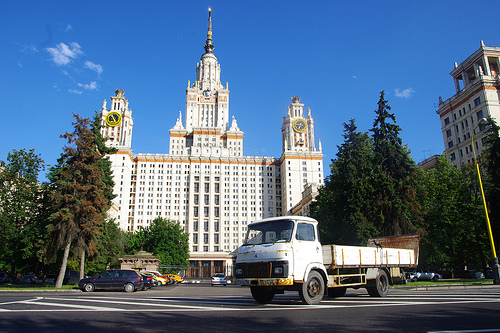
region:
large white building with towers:
[98, 9, 323, 286]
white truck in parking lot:
[229, 214, 421, 302]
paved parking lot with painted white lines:
[1, 282, 499, 331]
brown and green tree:
[41, 112, 117, 290]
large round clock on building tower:
[291, 118, 308, 133]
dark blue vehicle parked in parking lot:
[80, 268, 141, 291]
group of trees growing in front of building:
[311, 90, 491, 276]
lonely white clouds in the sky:
[44, 40, 106, 96]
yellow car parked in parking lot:
[168, 272, 181, 283]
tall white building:
[433, 40, 498, 167]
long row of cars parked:
[78, 266, 183, 294]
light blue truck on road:
[230, 215, 423, 302]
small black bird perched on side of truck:
[369, 233, 382, 253]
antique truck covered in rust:
[231, 215, 420, 282]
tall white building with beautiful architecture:
[100, 2, 325, 280]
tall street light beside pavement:
[471, 117, 498, 291]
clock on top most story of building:
[293, 119, 305, 132]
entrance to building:
[182, 253, 231, 286]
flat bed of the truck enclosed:
[322, 234, 419, 268]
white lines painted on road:
[2, 289, 498, 310]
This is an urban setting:
[26, 28, 353, 332]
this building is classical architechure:
[104, 8, 364, 220]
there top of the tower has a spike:
[181, 6, 243, 111]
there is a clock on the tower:
[288, 105, 320, 150]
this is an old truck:
[232, 182, 414, 302]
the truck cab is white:
[215, 193, 351, 298]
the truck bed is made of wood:
[312, 243, 417, 285]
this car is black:
[78, 250, 182, 298]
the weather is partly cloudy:
[45, 15, 332, 99]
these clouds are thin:
[26, 25, 134, 128]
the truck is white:
[212, 199, 446, 317]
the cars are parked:
[69, 255, 204, 303]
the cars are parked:
[43, 230, 224, 317]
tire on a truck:
[296, 266, 328, 305]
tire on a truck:
[367, 267, 396, 300]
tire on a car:
[122, 278, 132, 296]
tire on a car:
[80, 280, 96, 295]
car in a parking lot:
[210, 267, 230, 288]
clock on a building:
[289, 114, 309, 135]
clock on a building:
[100, 110, 123, 127]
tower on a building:
[273, 85, 327, 216]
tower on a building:
[92, 80, 139, 147]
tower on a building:
[162, 2, 245, 156]